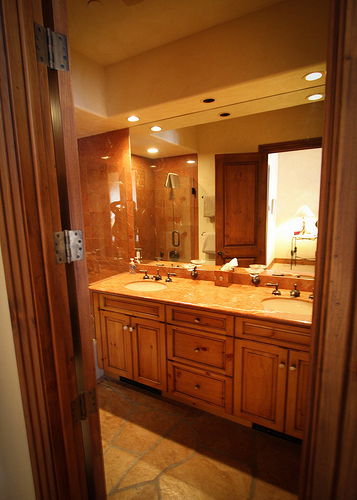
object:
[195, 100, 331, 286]
wall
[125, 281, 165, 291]
sink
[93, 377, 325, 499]
tile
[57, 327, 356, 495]
floor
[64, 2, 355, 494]
bathroom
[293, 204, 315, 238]
lamp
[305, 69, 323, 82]
light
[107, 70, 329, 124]
ceiling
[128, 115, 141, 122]
light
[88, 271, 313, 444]
cabinet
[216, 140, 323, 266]
door image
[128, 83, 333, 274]
mirror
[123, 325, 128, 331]
knob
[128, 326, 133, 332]
knob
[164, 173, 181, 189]
towel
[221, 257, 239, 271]
tissue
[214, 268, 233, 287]
box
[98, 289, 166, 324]
drawer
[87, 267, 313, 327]
counter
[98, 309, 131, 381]
drawer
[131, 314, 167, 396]
drawer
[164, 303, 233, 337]
drawer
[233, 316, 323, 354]
drawer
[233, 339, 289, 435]
drawer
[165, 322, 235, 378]
drawer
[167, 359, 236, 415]
drawer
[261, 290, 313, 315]
sink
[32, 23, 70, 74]
silver hinge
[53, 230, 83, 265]
silver hinge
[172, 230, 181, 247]
handle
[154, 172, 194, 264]
shower door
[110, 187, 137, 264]
reflection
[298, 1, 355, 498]
door frame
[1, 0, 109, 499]
door frame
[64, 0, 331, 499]
entry